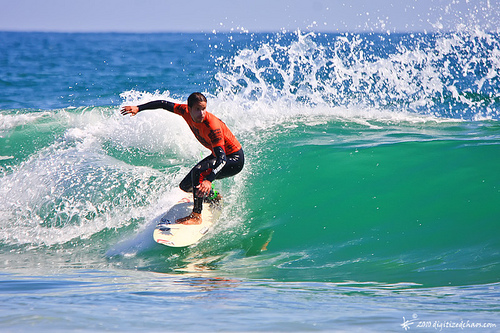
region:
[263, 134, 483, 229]
Beautiful blue green water.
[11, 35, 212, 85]
Gorgeous blue ocean water.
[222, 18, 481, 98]
White foam from the wave.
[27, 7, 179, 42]
Pale blue sky meets the ocean.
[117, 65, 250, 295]
Man on the surfboard.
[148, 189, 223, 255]
White surfboard in the ocean.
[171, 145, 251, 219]
Surfer wearing black pants.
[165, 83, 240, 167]
Surfer wearing red shirt.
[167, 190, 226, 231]
The surfer is barefoot.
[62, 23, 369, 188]
A very good day to surf.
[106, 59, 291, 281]
Man on a surfboard.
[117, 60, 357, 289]
Man in a wetsuit.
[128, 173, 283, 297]
White surfboard on the water.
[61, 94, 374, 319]
Ocean spray on the waves.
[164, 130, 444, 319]
Turquoise waters.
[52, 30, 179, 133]
Blue water in the background.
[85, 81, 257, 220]
White caps on the waves.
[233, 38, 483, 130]
Water spray in the air.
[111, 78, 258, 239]
Red and black wet suit.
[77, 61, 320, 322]
Man riding a wave.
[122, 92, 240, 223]
a person surfing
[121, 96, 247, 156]
a person wearing orange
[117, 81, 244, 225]
a person wearing orange and black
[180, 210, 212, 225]
bare feet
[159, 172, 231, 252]
a white surfboard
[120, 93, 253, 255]
a person wearing no shoes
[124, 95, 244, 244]
a person riding a white surfboard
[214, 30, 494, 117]
spray from the ocean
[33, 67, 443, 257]
a person surfing a wave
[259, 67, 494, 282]
a wave in the ocean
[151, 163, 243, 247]
white surfboard in water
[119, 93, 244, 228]
man has brown hair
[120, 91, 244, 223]
man is wearing red shirt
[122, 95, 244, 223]
man is wearing red shirt with black sleeves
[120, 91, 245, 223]
man is wearing black pants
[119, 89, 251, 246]
man is surfing in ocean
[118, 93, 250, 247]
man is surfing on white surfboard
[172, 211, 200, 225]
left foot on surfboard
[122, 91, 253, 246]
man surfing in the sea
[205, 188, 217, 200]
green strap around leg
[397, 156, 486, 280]
green water ocean wave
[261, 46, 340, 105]
White water splash above the ocean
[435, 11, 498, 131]
White water splash above the ocean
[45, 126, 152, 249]
White water splash above the ocean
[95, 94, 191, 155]
White water splash above the ocean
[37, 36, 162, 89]
A blue water surface